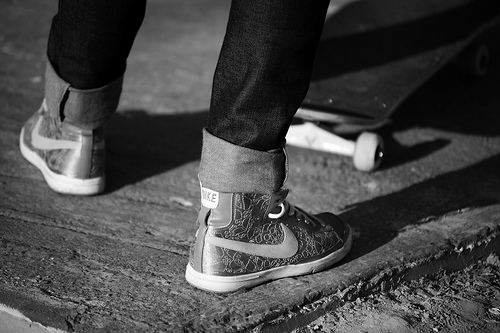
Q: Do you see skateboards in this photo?
A: Yes, there is a skateboard.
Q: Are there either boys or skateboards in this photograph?
A: Yes, there is a skateboard.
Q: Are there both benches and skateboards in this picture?
A: No, there is a skateboard but no benches.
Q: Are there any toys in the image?
A: No, there are no toys.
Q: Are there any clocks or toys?
A: No, there are no toys or clocks.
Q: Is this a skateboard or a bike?
A: This is a skateboard.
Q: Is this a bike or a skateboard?
A: This is a skateboard.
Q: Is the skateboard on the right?
A: Yes, the skateboard is on the right of the image.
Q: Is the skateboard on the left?
A: No, the skateboard is on the right of the image.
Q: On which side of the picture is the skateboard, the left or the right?
A: The skateboard is on the right of the image.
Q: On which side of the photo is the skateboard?
A: The skateboard is on the right of the image.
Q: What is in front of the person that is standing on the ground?
A: The skateboard is in front of the person.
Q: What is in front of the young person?
A: The skateboard is in front of the person.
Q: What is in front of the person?
A: The skateboard is in front of the person.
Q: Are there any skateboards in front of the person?
A: Yes, there is a skateboard in front of the person.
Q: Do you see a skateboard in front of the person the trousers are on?
A: Yes, there is a skateboard in front of the person.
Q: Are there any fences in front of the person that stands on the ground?
A: No, there is a skateboard in front of the person.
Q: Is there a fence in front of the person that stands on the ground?
A: No, there is a skateboard in front of the person.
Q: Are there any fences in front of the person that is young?
A: No, there is a skateboard in front of the person.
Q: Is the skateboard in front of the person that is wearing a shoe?
A: Yes, the skateboard is in front of the person.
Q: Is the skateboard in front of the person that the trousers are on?
A: Yes, the skateboard is in front of the person.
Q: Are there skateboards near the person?
A: Yes, there is a skateboard near the person.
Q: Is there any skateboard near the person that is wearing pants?
A: Yes, there is a skateboard near the person.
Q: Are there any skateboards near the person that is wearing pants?
A: Yes, there is a skateboard near the person.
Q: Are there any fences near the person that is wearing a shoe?
A: No, there is a skateboard near the person.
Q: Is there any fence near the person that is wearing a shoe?
A: No, there is a skateboard near the person.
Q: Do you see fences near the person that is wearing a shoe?
A: No, there is a skateboard near the person.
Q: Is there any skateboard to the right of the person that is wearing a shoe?
A: Yes, there is a skateboard to the right of the person.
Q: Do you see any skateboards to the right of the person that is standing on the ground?
A: Yes, there is a skateboard to the right of the person.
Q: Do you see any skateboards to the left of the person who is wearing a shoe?
A: No, the skateboard is to the right of the person.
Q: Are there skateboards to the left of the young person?
A: No, the skateboard is to the right of the person.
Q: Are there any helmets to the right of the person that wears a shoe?
A: No, there is a skateboard to the right of the person.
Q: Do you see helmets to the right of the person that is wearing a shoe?
A: No, there is a skateboard to the right of the person.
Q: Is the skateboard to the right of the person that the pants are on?
A: Yes, the skateboard is to the right of the person.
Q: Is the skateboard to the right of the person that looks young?
A: Yes, the skateboard is to the right of the person.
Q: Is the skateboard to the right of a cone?
A: No, the skateboard is to the right of the person.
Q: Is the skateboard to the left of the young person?
A: No, the skateboard is to the right of the person.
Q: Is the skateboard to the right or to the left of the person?
A: The skateboard is to the right of the person.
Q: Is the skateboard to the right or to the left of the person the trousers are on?
A: The skateboard is to the right of the person.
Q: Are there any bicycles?
A: No, there are no bicycles.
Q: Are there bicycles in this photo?
A: No, there are no bicycles.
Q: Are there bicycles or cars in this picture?
A: No, there are no bicycles or cars.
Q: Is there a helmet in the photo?
A: No, there are no helmets.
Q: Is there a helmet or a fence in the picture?
A: No, there are no helmets or fences.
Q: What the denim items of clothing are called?
A: The clothing items are pants.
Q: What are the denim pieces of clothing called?
A: The clothing items are pants.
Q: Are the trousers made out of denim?
A: Yes, the trousers are made of denim.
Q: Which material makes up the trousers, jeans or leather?
A: The trousers are made of jeans.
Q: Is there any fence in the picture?
A: No, there are no fences.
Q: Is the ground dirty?
A: Yes, the ground is dirty.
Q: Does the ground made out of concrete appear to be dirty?
A: Yes, the ground is dirty.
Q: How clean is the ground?
A: The ground is dirty.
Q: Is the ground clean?
A: No, the ground is dirty.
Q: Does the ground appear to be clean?
A: No, the ground is dirty.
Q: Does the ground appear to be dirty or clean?
A: The ground is dirty.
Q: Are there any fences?
A: No, there are no fences.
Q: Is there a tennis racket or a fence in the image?
A: No, there are no fences or rackets.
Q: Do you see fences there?
A: No, there are no fences.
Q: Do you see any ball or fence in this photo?
A: No, there are no fences or balls.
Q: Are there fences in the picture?
A: No, there are no fences.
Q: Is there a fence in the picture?
A: No, there are no fences.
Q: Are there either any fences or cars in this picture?
A: No, there are no fences or cars.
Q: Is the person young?
A: Yes, the person is young.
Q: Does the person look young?
A: Yes, the person is young.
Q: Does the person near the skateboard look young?
A: Yes, the person is young.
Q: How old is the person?
A: The person is young.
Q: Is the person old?
A: No, the person is young.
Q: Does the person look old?
A: No, the person is young.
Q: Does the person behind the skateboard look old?
A: No, the person is young.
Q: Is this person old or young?
A: The person is young.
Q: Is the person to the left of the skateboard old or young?
A: The person is young.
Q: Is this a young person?
A: Yes, this is a young person.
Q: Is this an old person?
A: No, this is a young person.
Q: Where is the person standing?
A: The person is standing on the ground.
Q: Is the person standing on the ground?
A: Yes, the person is standing on the ground.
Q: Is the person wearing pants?
A: Yes, the person is wearing pants.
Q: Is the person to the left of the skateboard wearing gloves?
A: No, the person is wearing pants.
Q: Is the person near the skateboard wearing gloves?
A: No, the person is wearing pants.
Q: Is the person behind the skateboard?
A: Yes, the person is behind the skateboard.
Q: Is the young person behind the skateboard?
A: Yes, the person is behind the skateboard.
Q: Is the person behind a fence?
A: No, the person is behind the skateboard.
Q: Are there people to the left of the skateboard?
A: Yes, there is a person to the left of the skateboard.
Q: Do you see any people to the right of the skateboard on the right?
A: No, the person is to the left of the skateboard.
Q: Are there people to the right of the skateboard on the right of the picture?
A: No, the person is to the left of the skateboard.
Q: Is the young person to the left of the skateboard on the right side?
A: Yes, the person is to the left of the skateboard.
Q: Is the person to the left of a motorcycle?
A: No, the person is to the left of the skateboard.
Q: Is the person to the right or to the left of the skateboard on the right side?
A: The person is to the left of the skateboard.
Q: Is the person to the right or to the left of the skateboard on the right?
A: The person is to the left of the skateboard.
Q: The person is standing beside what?
A: The person is standing beside the skateboard.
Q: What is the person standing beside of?
A: The person is standing beside the skateboard.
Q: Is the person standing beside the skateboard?
A: Yes, the person is standing beside the skateboard.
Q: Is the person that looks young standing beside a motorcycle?
A: No, the person is standing beside the skateboard.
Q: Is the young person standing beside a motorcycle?
A: No, the person is standing beside the skateboard.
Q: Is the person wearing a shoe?
A: Yes, the person is wearing a shoe.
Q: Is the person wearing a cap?
A: No, the person is wearing a shoe.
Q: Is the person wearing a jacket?
A: No, the person is wearing a shoe.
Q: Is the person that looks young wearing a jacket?
A: No, the person is wearing a shoe.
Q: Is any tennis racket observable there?
A: No, there are no rackets.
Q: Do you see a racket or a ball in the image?
A: No, there are no rackets or balls.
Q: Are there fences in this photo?
A: No, there are no fences.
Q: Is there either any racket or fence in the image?
A: No, there are no fences or rackets.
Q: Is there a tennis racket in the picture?
A: No, there are no rackets.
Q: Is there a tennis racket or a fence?
A: No, there are no rackets or fences.